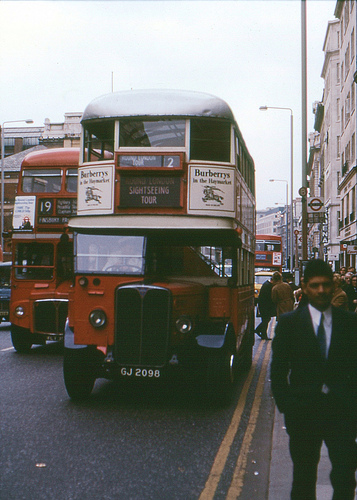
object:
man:
[268, 253, 354, 499]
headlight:
[176, 314, 193, 335]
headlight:
[88, 306, 108, 330]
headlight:
[15, 305, 27, 317]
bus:
[56, 83, 264, 407]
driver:
[102, 235, 143, 274]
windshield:
[72, 230, 146, 276]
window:
[117, 115, 186, 149]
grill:
[109, 281, 174, 373]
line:
[220, 339, 278, 497]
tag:
[109, 364, 164, 380]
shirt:
[309, 307, 335, 354]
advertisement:
[72, 156, 119, 219]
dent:
[202, 109, 210, 118]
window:
[189, 115, 230, 163]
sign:
[117, 175, 180, 207]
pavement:
[268, 425, 288, 500]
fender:
[193, 319, 237, 352]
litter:
[245, 455, 266, 482]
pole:
[298, 1, 309, 274]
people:
[254, 263, 297, 342]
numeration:
[160, 152, 184, 171]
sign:
[305, 197, 324, 214]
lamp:
[258, 105, 270, 114]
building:
[318, 3, 342, 267]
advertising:
[10, 189, 39, 234]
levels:
[67, 219, 231, 236]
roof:
[79, 90, 227, 121]